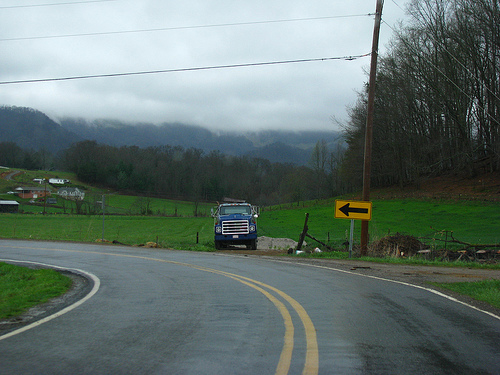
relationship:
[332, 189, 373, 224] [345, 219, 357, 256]
sign on pole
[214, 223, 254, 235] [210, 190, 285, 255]
headlights on truck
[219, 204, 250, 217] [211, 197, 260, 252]
window of car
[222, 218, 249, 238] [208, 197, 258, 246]
grill of truck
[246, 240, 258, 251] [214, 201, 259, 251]
tire of truck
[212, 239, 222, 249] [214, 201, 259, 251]
tire of truck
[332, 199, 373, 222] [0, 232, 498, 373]
sign on side of road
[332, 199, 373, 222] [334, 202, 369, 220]
sign with arrow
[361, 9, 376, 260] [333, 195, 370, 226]
pole behind sign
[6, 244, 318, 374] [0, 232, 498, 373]
stripes on road